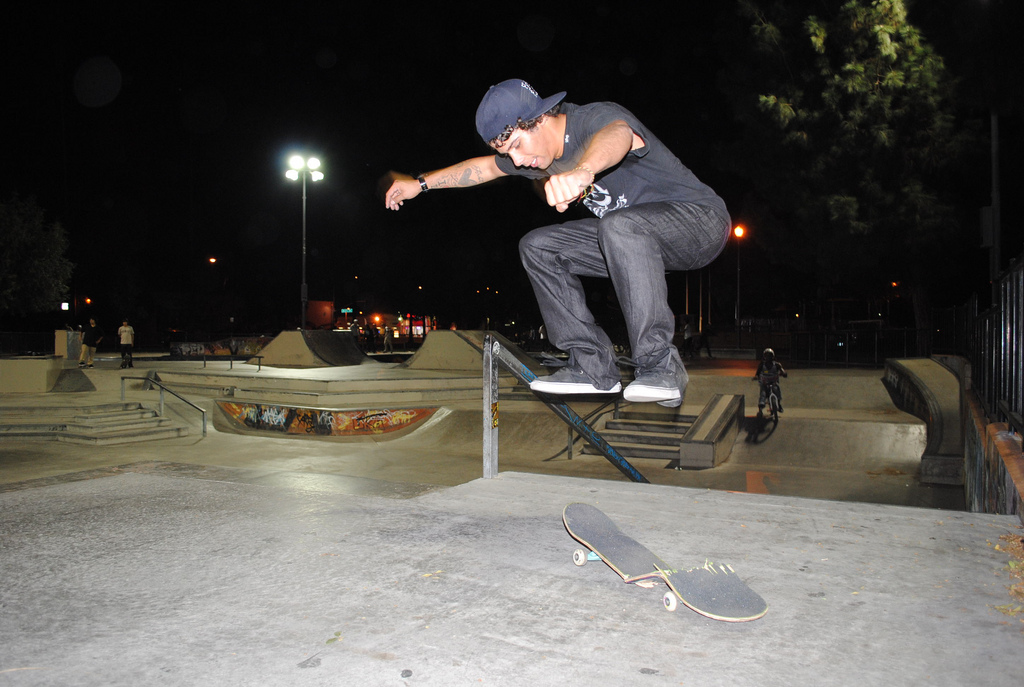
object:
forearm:
[422, 155, 498, 189]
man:
[384, 79, 734, 403]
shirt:
[492, 101, 720, 219]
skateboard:
[562, 503, 768, 623]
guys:
[118, 321, 134, 369]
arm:
[384, 154, 551, 211]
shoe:
[529, 351, 622, 395]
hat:
[474, 78, 569, 147]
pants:
[517, 194, 733, 390]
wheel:
[573, 549, 587, 566]